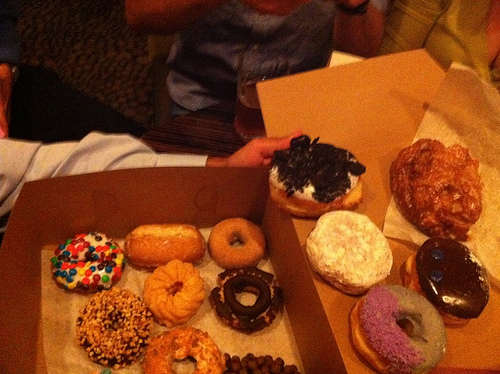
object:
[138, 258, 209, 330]
donuts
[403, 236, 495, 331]
donut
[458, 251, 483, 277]
cream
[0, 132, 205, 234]
sweater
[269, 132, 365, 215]
donut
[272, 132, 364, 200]
topping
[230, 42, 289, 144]
glass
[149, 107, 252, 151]
table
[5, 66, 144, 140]
pants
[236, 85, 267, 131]
full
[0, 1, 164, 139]
people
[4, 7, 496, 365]
photo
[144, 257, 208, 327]
doughnut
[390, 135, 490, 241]
doughnut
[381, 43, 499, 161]
corner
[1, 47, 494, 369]
box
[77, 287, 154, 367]
doughnut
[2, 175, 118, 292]
corner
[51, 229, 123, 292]
donut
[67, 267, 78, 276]
candies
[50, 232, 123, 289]
top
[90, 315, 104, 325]
peanuts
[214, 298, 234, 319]
chocolate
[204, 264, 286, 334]
doughnut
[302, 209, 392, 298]
powder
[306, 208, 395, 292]
donut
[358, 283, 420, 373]
sprinkles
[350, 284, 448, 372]
donut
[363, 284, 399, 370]
purple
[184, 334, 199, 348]
cookie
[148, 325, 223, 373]
donut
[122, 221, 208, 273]
doughnut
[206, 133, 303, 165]
hand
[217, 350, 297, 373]
donuts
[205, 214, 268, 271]
plain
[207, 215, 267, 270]
donut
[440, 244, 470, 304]
chocolate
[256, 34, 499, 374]
lid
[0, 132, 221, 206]
arm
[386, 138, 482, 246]
sticky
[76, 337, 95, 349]
chocolate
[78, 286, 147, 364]
top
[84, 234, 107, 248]
cream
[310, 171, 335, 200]
cookie